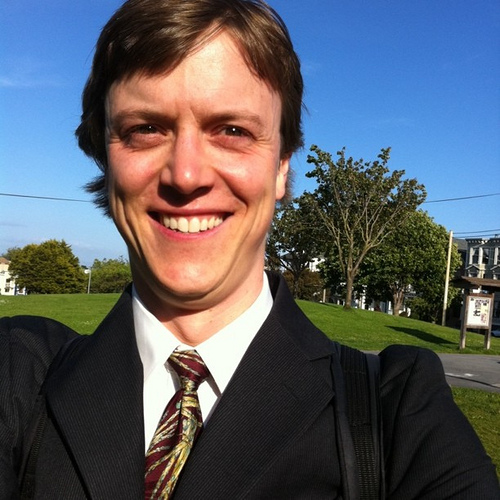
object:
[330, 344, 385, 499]
strap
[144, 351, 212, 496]
tie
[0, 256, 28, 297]
building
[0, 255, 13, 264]
roof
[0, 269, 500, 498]
jacket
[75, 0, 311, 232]
hair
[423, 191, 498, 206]
line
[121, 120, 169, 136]
eyes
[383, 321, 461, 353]
shadow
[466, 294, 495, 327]
sign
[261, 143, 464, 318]
trees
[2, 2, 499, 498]
guy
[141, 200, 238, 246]
smile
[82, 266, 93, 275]
flag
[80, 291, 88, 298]
hole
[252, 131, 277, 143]
wrinkles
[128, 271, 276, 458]
shirt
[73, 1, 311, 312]
head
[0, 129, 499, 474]
background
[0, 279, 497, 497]
suit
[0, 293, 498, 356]
grass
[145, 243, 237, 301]
chin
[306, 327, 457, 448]
shoulder